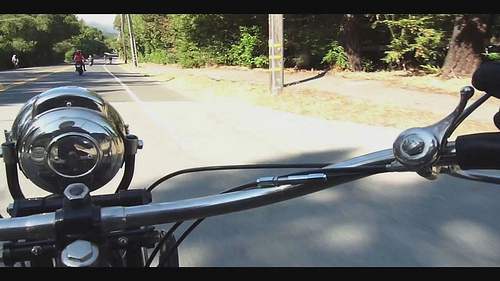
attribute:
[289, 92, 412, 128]
grass — green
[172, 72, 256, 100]
grass — green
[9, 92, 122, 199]
headlight — silver, chrome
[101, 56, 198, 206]
line — white, painted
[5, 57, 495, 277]
road — grey, long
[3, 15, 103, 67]
trees — thick, green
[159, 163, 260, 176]
wire — black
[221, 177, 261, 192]
wire — black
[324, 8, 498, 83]
tree — large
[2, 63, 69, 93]
line — yellow, double, painted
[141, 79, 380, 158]
road — light grey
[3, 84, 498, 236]
handlebar — chrome, silver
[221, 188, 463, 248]
shadow — large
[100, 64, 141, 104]
strip — white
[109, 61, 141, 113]
line — white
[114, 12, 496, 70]
trees — green, bunch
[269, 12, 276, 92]
pole — brown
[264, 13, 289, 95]
pole — telephone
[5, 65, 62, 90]
line — yellow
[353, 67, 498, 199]
handle — black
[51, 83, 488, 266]
handlebar — silver, black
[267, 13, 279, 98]
pole — brown, white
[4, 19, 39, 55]
tree — green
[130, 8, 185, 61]
tree — green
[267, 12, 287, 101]
post — wooden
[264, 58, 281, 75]
line — yellow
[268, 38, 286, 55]
line — yellow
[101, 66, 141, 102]
line — yellow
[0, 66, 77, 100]
line — yellow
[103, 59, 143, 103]
line — white, painted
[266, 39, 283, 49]
mark — yellow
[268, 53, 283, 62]
mark — yellow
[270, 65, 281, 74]
mark — yellow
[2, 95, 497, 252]
handle bar — silver, chrome